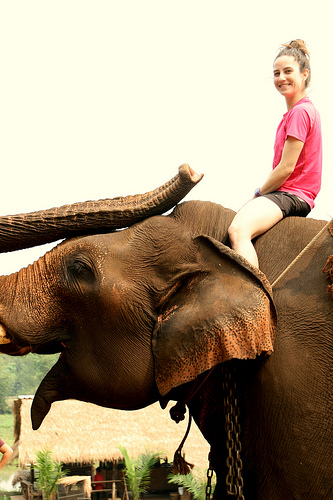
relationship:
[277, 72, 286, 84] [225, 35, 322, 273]
nose on lady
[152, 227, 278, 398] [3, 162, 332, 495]
ear of elephant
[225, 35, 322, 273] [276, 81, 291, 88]
lady has mouth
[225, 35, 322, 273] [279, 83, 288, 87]
lady has teeth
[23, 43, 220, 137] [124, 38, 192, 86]
clouds in sky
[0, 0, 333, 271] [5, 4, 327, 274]
clouds in sky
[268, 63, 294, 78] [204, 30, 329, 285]
eyes of woman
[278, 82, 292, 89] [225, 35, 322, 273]
lips of lady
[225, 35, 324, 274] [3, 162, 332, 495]
lady sitting on elephant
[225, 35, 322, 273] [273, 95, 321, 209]
lady wearing shirt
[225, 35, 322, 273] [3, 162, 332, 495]
lady on elephant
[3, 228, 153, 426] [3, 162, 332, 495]
face of elephant